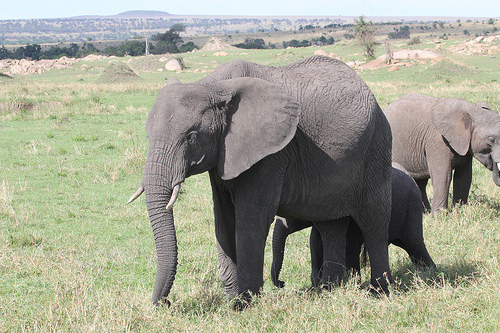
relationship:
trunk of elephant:
[142, 145, 178, 308] [122, 53, 392, 313]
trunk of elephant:
[491, 142, 499, 186] [381, 90, 500, 219]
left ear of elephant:
[215, 74, 305, 182] [122, 53, 392, 313]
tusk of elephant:
[166, 181, 182, 212] [122, 53, 392, 313]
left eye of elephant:
[186, 130, 199, 142] [122, 53, 392, 313]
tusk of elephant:
[125, 185, 145, 205] [122, 53, 392, 313]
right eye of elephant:
[292, 218, 300, 223] [269, 159, 443, 291]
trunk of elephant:
[270, 217, 286, 289] [269, 159, 443, 291]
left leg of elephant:
[226, 151, 289, 313] [122, 53, 392, 313]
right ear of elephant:
[430, 96, 474, 158] [381, 90, 500, 219]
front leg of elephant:
[209, 179, 240, 299] [122, 53, 392, 313]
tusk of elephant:
[495, 160, 500, 176] [381, 90, 500, 219]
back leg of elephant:
[354, 180, 399, 297] [122, 53, 392, 313]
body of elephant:
[211, 56, 389, 221] [122, 53, 392, 313]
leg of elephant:
[423, 134, 454, 219] [381, 90, 500, 219]